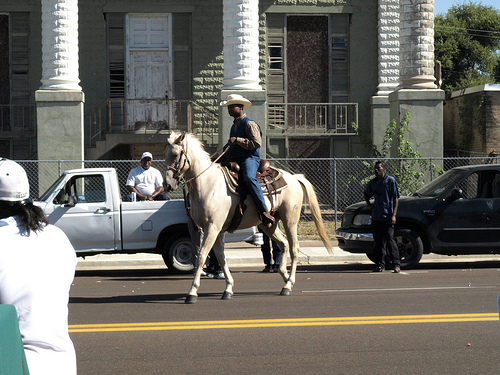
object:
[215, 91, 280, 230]
man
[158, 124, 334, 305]
horse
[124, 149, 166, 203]
man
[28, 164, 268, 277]
truck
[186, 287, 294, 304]
hooves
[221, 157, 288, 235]
saddle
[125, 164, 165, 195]
shirt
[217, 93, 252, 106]
cowboy hat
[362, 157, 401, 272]
man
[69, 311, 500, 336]
lines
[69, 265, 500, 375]
street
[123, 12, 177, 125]
door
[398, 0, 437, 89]
pillar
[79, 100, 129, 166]
stairs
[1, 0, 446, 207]
building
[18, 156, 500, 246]
fence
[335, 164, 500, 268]
suv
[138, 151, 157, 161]
hat